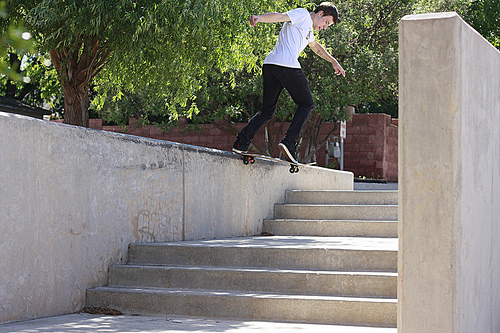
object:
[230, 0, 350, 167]
man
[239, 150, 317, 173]
board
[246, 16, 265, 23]
hand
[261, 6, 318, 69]
shirt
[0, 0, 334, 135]
tree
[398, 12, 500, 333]
wall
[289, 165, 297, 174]
wheels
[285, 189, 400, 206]
steps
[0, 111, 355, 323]
wall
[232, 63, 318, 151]
pants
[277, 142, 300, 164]
shoes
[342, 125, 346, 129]
lettering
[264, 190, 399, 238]
stairs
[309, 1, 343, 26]
hair